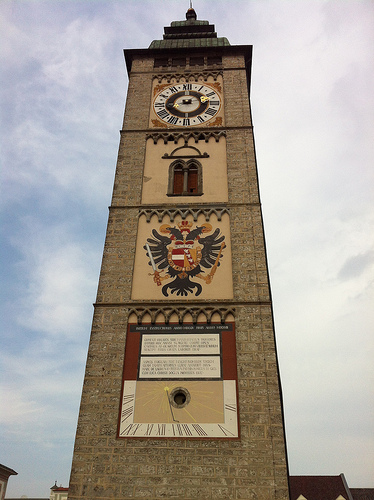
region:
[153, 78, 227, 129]
A large clock on the building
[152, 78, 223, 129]
The clock is shaped like a circle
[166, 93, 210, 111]
The hands of the circular clock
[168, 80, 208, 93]
Black numbers inscribed on the clock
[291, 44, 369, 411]
Thick white clouds in the sky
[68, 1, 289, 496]
A tall clock tower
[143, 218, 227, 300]
An intricate mural on the wall of the clock tower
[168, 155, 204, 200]
Two small windows on the clock tower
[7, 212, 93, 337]
A wispy white cloud in the sky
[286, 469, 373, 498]
The roof of a distant building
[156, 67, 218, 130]
clock on large tower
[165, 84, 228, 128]
clock has roman numerals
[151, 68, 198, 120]
white and black clock face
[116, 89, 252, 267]
tower is brown brick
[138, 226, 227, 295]
bird deity on tower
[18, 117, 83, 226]
blue and white sky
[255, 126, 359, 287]
heavy clouds on right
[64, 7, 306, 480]
tower with clock on it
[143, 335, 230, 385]
lettering on the tower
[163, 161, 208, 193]
double door image under arch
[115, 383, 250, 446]
graphic image on plaque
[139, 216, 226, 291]
image with a sword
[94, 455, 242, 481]
brick on the tower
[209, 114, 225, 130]
creature in corner of clock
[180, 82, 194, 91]
roman numeral on the clock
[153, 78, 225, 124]
The clock at the top of the tower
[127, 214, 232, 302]
A picture of two birds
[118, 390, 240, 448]
The clock has roman numerals on it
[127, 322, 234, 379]
The plaques on the wall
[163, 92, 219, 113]
The hands on the clock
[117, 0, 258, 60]
The top of the building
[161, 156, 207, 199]
The window is on the side of the building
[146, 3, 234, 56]
The top of the building is green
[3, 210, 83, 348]
Clouds in the sky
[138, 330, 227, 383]
Words written on a monument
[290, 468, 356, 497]
Rooftop of a building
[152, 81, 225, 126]
Clock with roman numerals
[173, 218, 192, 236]
Crown drawn on a monument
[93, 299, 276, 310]
A ridge on a monument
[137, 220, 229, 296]
Drawing of a shield on a monument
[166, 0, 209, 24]
The peak of a monument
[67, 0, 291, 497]
A tall narrow monument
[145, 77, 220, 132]
black white and gold clock in tower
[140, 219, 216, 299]
crest on clock tower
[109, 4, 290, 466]
tan clock tower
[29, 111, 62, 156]
white clouds in blue sky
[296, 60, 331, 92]
white clouds in blue sky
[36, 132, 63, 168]
white clouds in blue sky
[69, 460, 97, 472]
a stone in a wall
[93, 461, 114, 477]
a stone in a wall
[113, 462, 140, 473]
a stone in a wall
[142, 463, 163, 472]
a stone in a wall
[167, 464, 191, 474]
a stone in a wall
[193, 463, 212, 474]
a stone in a wall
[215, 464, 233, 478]
a stone in a wall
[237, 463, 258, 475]
a stone in a wall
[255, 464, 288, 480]
a stone in a wall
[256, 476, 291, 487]
a stone in a wall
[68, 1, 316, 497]
a large brick tower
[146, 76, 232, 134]
clock on a tower